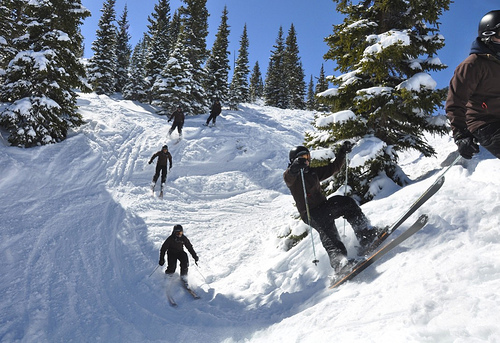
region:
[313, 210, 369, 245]
Black pants of second skier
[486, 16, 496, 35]
Black helmet of the first skier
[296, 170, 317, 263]
Right ski pole of the second skier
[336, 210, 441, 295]
Right ski of second skier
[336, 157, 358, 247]
Left ski of second skier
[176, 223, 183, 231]
Black helmet of third skier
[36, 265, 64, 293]
Ski tracks in the snow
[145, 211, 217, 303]
skier on hill side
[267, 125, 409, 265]
skier on hill side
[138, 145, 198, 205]
skier on hill side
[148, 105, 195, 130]
skier on hill side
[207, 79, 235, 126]
skier on hill side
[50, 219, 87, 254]
white snow on hill side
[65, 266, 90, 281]
white snow on hill side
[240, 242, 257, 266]
white snow on hill side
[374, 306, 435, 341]
white snow on hill side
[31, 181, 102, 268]
white snow on hill side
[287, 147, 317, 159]
Person wearing black helmet.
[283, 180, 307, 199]
Person wearing black coat.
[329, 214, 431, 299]
2 skis on person's feet.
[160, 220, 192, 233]
Person wearing black helmet.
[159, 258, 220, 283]
Person holding 2 ski poles.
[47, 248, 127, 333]
Ground covered in white snow.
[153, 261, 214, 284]
Person wearing black pants.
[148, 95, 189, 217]
two people skiing downhill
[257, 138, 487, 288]
a person skiing uphill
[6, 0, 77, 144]
snow on the trees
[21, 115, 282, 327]
snow covering the ground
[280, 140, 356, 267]
the person is holding ski poles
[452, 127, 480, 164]
the glove is black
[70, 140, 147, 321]
tracks in the snow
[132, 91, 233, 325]
four people skiing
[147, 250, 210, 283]
two ski poles in the person's hand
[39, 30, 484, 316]
skiers on the slopes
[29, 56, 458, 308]
they are skiing over rugged terrain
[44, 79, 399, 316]
this area is extremely hilly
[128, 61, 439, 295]
there are five skiers in this shot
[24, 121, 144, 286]
the are is messy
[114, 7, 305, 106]
the pine trees have snow on them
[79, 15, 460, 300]
sun is shining on the ski course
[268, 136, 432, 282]
skiier coming down a hill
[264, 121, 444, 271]
skiier jamming down a hill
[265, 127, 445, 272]
skier racing down a hill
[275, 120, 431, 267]
skier boosting down a hill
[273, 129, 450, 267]
skier skiing down a hill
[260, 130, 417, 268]
skier on skis coming down a hill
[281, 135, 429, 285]
skier carving powder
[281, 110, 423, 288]
skier going down hill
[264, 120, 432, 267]
skier cutting a path down a hill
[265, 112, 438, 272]
skier preparing to go off a jump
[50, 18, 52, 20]
A green leaf on a plant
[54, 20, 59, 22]
A green leaf on a plant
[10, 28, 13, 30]
A green leaf on a plant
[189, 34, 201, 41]
A green leaf on a plant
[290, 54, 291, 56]
A green leaf on a plant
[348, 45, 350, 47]
A green leaf on a plant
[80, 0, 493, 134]
The clear blue sky